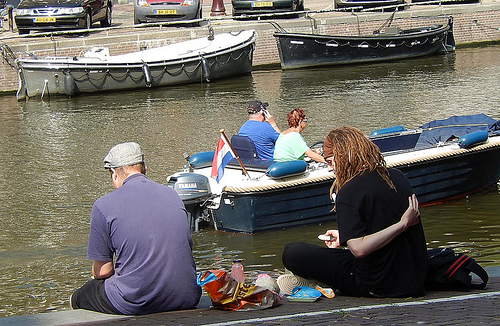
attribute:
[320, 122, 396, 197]
hair — dreadlocked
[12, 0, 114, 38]
car — parked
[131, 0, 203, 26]
car — parked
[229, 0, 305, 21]
car — parked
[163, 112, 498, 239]
boat — blue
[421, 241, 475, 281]
bag — black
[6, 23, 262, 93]
boat — gray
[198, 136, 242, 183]
flag — red, white, blue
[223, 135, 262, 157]
backrest — blue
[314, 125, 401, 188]
hair — long, brown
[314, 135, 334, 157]
band — brown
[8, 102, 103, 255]
sea — pictured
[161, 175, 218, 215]
motor — blue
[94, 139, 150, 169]
hat — gray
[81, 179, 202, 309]
shirt — purple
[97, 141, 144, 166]
hat — white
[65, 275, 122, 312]
pants — black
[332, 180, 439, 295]
shirt — black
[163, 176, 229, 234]
motor — outboard 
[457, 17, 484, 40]
wall — red bricked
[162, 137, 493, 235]
boat — blue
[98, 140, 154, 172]
cap — colorless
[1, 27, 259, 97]
boat — parked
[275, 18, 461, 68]
boat — parked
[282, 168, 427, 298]
clothing — black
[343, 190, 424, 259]
left hand — extended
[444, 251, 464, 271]
stripe — orange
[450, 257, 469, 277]
stripe — orange